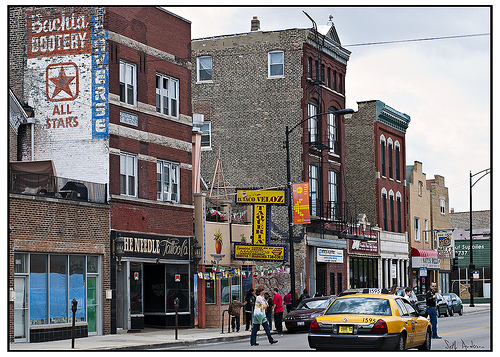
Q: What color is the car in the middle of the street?
A: Yellow.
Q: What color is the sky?
A: Blue and white.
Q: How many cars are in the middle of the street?
A: One.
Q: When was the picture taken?
A: Daytime.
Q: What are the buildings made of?
A: Bricks.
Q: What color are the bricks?
A: Red.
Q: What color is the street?
A: Black.